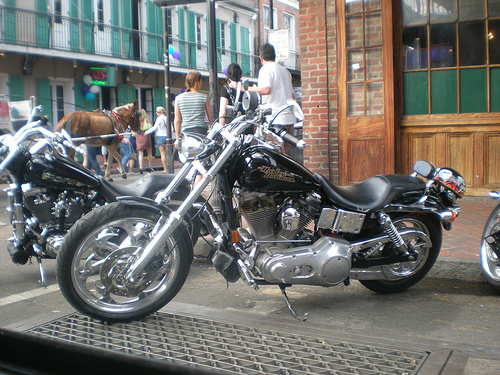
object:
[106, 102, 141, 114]
mane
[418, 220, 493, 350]
ground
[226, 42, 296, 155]
man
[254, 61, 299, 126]
shirt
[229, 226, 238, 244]
reflector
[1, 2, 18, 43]
door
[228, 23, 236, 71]
door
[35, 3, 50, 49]
door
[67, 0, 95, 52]
door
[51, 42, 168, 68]
floor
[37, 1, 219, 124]
hotel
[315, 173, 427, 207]
seat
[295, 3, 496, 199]
building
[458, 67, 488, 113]
window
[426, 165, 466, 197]
helmet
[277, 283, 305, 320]
kick stand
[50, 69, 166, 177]
horse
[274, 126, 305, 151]
handlebar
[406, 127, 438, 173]
panel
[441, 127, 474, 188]
panel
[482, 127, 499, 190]
panel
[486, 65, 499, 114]
window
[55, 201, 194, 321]
black tire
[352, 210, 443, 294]
black tire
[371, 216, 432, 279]
rim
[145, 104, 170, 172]
person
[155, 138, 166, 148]
shorts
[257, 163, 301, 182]
brand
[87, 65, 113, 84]
neon sign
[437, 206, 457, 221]
taillight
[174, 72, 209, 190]
people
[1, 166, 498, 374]
street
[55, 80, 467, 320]
harley davidson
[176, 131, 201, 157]
headlight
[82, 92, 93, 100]
balloons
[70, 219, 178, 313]
rim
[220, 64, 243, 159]
woman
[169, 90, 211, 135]
striped shirt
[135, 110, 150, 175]
woman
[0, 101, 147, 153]
buggy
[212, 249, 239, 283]
detailing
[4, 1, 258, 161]
building